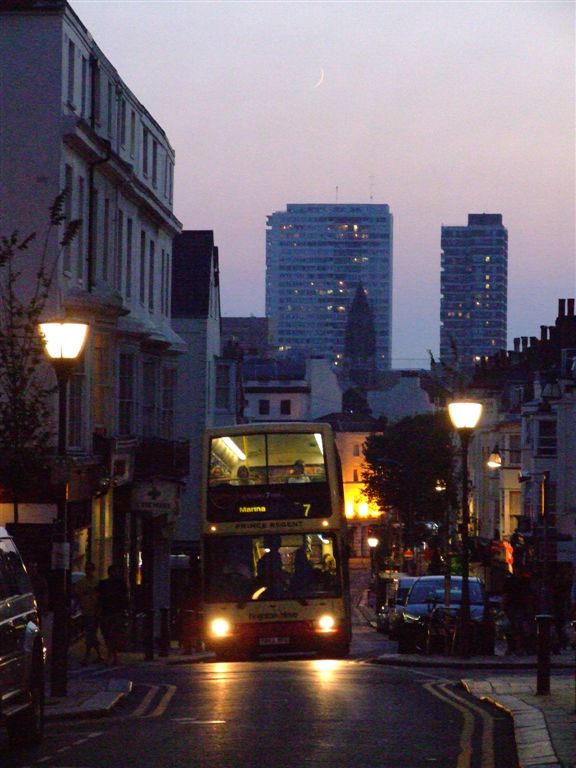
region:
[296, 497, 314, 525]
the number 7 on the bus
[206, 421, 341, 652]
the double decker bus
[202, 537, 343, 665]
the bottom of the bus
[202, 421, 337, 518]
the top of the bus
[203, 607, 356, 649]
the headlights on the bus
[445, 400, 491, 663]
the yellow street lamp next to the bus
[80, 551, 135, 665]
the people walking across the street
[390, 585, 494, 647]
the car parked next to the bus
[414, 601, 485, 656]
the bikes parked next to the bus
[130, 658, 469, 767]
the street in front of the bus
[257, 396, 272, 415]
window on building facing busy street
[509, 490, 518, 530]
window on building facing busy street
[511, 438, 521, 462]
window on building facing busy street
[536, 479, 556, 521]
window on building facing busy street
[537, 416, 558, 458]
window on building facing busy street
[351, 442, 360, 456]
window on building facing busy street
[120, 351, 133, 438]
window on building facing busy street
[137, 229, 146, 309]
window on building facing busy street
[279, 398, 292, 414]
window on building facing busy street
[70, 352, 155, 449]
window on building facing busy street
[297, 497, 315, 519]
number 7 on the bus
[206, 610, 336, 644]
headlights on the front of the bus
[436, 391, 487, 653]
lamp on a light post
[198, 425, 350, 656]
double decker bus on the road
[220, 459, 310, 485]
two people on the bus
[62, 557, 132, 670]
people walking on the sidewalk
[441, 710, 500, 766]
yellow lines on the road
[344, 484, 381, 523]
lights on the building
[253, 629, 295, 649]
license plate on the front of the bus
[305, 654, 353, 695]
light on the street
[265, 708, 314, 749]
the street is black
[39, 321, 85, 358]
a street light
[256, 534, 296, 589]
person standing on the bus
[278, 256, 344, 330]
windows on the building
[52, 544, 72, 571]
a sign on the pole